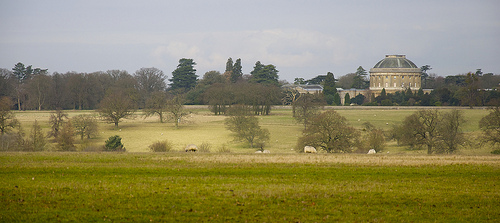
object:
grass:
[1, 145, 499, 219]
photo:
[1, 1, 499, 222]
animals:
[366, 147, 379, 156]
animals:
[302, 142, 318, 155]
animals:
[183, 147, 202, 154]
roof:
[369, 52, 417, 72]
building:
[363, 46, 427, 102]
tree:
[166, 57, 202, 99]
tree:
[103, 133, 130, 156]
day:
[1, 2, 500, 96]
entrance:
[338, 86, 361, 106]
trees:
[291, 86, 336, 130]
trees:
[64, 113, 100, 145]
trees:
[94, 75, 141, 131]